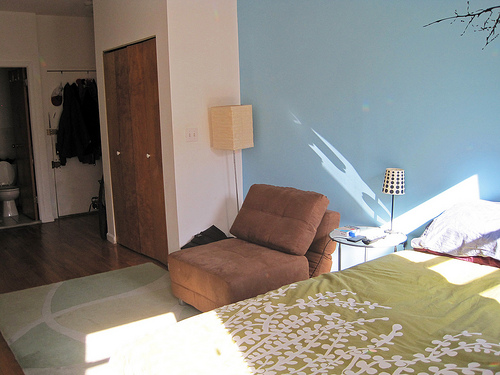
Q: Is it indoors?
A: Yes, it is indoors.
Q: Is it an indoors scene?
A: Yes, it is indoors.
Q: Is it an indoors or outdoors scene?
A: It is indoors.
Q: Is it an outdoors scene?
A: No, it is indoors.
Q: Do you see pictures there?
A: No, there are no pictures.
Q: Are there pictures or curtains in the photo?
A: No, there are no pictures or curtains.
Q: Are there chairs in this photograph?
A: Yes, there is a chair.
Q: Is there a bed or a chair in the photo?
A: Yes, there is a chair.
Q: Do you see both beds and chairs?
A: Yes, there are both a chair and a bed.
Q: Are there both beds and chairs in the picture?
A: Yes, there are both a chair and a bed.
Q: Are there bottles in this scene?
A: No, there are no bottles.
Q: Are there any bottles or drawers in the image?
A: No, there are no bottles or drawers.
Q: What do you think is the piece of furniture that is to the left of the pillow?
A: The piece of furniture is a chair.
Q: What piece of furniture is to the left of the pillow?
A: The piece of furniture is a chair.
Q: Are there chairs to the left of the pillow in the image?
A: Yes, there is a chair to the left of the pillow.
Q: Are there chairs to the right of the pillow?
A: No, the chair is to the left of the pillow.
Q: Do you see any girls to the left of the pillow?
A: No, there is a chair to the left of the pillow.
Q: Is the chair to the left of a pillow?
A: Yes, the chair is to the left of a pillow.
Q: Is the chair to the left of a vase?
A: No, the chair is to the left of a pillow.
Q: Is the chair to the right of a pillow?
A: No, the chair is to the left of a pillow.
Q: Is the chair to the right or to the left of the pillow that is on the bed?
A: The chair is to the left of the pillow.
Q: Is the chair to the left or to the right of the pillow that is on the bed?
A: The chair is to the left of the pillow.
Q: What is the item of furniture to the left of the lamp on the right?
A: The piece of furniture is a chair.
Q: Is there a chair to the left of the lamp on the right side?
A: Yes, there is a chair to the left of the lamp.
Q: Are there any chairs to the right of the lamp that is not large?
A: No, the chair is to the left of the lamp.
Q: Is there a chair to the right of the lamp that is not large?
A: No, the chair is to the left of the lamp.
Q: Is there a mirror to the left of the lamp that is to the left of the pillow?
A: No, there is a chair to the left of the lamp.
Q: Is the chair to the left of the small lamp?
A: Yes, the chair is to the left of the lamp.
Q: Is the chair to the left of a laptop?
A: No, the chair is to the left of the lamp.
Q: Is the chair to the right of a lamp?
A: No, the chair is to the left of a lamp.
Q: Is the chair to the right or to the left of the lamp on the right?
A: The chair is to the left of the lamp.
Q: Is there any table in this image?
A: Yes, there is a table.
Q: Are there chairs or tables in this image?
A: Yes, there is a table.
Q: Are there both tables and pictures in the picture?
A: No, there is a table but no pictures.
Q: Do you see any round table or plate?
A: Yes, there is a round table.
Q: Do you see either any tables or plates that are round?
A: Yes, the table is round.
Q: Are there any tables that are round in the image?
A: Yes, there is a round table.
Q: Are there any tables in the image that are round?
A: Yes, there is a table that is round.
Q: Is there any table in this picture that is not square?
A: Yes, there is a round table.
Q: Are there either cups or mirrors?
A: No, there are no mirrors or cups.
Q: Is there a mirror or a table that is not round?
A: No, there is a table but it is round.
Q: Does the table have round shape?
A: Yes, the table is round.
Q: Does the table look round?
A: Yes, the table is round.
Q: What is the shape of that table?
A: The table is round.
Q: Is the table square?
A: No, the table is round.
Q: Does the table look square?
A: No, the table is round.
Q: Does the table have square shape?
A: No, the table is round.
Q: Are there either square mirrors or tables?
A: No, there is a table but it is round.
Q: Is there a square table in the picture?
A: No, there is a table but it is round.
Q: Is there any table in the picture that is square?
A: No, there is a table but it is round.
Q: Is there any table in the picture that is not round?
A: No, there is a table but it is round.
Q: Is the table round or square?
A: The table is round.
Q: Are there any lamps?
A: Yes, there is a lamp.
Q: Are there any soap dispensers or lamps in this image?
A: Yes, there is a lamp.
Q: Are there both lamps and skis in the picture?
A: No, there is a lamp but no skis.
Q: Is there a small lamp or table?
A: Yes, there is a small lamp.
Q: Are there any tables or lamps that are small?
A: Yes, the lamp is small.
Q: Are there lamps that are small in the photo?
A: Yes, there is a small lamp.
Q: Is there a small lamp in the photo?
A: Yes, there is a small lamp.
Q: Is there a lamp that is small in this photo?
A: Yes, there is a small lamp.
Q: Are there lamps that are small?
A: Yes, there is a lamp that is small.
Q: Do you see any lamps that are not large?
A: Yes, there is a small lamp.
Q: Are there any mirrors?
A: No, there are no mirrors.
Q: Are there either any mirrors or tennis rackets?
A: No, there are no mirrors or tennis rackets.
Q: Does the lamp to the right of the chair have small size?
A: Yes, the lamp is small.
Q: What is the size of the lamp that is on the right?
A: The lamp is small.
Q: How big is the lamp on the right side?
A: The lamp is small.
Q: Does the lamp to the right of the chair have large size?
A: No, the lamp is small.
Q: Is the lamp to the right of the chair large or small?
A: The lamp is small.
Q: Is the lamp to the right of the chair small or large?
A: The lamp is small.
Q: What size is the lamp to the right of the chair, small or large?
A: The lamp is small.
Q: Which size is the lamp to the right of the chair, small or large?
A: The lamp is small.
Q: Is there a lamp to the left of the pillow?
A: Yes, there is a lamp to the left of the pillow.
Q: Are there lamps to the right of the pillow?
A: No, the lamp is to the left of the pillow.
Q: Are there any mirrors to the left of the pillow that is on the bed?
A: No, there is a lamp to the left of the pillow.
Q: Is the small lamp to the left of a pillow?
A: Yes, the lamp is to the left of a pillow.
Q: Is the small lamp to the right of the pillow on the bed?
A: No, the lamp is to the left of the pillow.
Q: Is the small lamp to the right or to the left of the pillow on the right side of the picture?
A: The lamp is to the left of the pillow.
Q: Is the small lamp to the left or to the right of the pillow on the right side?
A: The lamp is to the left of the pillow.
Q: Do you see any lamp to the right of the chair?
A: Yes, there is a lamp to the right of the chair.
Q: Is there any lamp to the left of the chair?
A: No, the lamp is to the right of the chair.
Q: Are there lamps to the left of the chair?
A: No, the lamp is to the right of the chair.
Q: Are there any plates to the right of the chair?
A: No, there is a lamp to the right of the chair.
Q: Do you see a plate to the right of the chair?
A: No, there is a lamp to the right of the chair.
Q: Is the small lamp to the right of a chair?
A: Yes, the lamp is to the right of a chair.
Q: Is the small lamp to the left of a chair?
A: No, the lamp is to the right of a chair.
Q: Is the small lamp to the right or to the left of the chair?
A: The lamp is to the right of the chair.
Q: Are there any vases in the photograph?
A: No, there are no vases.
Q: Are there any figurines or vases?
A: No, there are no vases or figurines.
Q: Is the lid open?
A: Yes, the lid is open.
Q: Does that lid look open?
A: Yes, the lid is open.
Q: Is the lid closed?
A: No, the lid is open.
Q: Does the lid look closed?
A: No, the lid is open.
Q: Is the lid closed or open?
A: The lid is open.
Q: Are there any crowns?
A: No, there are no crowns.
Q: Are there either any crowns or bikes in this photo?
A: No, there are no crowns or bikes.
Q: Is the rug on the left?
A: Yes, the rug is on the left of the image.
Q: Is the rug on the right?
A: No, the rug is on the left of the image.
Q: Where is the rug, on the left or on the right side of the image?
A: The rug is on the left of the image.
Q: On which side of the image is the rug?
A: The rug is on the left of the image.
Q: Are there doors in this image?
A: Yes, there is a door.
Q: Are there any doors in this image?
A: Yes, there is a door.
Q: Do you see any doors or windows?
A: Yes, there is a door.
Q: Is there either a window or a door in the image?
A: Yes, there is a door.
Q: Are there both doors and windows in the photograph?
A: No, there is a door but no windows.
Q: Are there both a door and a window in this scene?
A: No, there is a door but no windows.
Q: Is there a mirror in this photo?
A: No, there are no mirrors.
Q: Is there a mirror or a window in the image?
A: No, there are no mirrors or windows.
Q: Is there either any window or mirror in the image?
A: No, there are no mirrors or windows.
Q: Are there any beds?
A: Yes, there is a bed.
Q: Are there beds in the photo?
A: Yes, there is a bed.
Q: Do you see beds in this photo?
A: Yes, there is a bed.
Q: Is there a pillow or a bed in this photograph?
A: Yes, there is a bed.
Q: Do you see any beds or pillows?
A: Yes, there is a bed.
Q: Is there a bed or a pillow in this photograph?
A: Yes, there is a bed.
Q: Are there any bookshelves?
A: No, there are no bookshelves.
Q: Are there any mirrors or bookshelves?
A: No, there are no bookshelves or mirrors.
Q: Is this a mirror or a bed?
A: This is a bed.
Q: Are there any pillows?
A: Yes, there is a pillow.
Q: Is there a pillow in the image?
A: Yes, there is a pillow.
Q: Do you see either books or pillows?
A: Yes, there is a pillow.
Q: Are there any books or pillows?
A: Yes, there is a pillow.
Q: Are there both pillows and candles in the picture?
A: No, there is a pillow but no candles.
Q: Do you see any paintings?
A: No, there are no paintings.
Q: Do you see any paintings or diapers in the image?
A: No, there are no paintings or diapers.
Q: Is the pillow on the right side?
A: Yes, the pillow is on the right of the image.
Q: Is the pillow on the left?
A: No, the pillow is on the right of the image.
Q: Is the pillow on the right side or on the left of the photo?
A: The pillow is on the right of the image.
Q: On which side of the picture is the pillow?
A: The pillow is on the right of the image.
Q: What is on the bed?
A: The pillow is on the bed.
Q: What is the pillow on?
A: The pillow is on the bed.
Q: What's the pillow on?
A: The pillow is on the bed.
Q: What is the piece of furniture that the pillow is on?
A: The piece of furniture is a bed.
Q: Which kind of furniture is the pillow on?
A: The pillow is on the bed.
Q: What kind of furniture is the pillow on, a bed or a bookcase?
A: The pillow is on a bed.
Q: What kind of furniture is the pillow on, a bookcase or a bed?
A: The pillow is on a bed.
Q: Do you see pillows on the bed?
A: Yes, there is a pillow on the bed.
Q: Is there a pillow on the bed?
A: Yes, there is a pillow on the bed.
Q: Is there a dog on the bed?
A: No, there is a pillow on the bed.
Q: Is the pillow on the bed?
A: Yes, the pillow is on the bed.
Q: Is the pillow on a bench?
A: No, the pillow is on the bed.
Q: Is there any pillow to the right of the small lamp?
A: Yes, there is a pillow to the right of the lamp.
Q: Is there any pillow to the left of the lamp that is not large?
A: No, the pillow is to the right of the lamp.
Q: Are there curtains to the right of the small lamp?
A: No, there is a pillow to the right of the lamp.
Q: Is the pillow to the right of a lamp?
A: Yes, the pillow is to the right of a lamp.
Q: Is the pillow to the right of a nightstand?
A: No, the pillow is to the right of a lamp.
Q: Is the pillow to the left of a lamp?
A: No, the pillow is to the right of a lamp.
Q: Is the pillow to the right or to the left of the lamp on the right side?
A: The pillow is to the right of the lamp.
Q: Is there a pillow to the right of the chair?
A: Yes, there is a pillow to the right of the chair.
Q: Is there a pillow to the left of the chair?
A: No, the pillow is to the right of the chair.